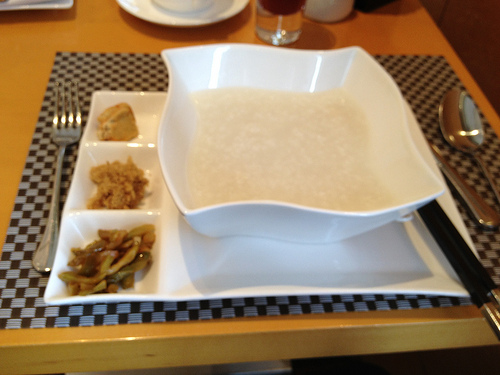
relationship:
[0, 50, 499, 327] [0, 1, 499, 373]
placemat on table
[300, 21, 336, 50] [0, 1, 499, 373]
shadow on table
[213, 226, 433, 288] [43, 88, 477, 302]
shadow on plate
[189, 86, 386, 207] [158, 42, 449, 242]
soup in bowl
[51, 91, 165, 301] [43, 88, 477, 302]
sections on plate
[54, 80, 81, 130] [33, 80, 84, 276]
tines on fork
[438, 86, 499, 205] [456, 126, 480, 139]
spoon reflecting light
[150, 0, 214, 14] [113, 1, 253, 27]
mug on saucer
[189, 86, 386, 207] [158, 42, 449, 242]
soup inside bowl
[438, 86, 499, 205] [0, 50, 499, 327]
spoon on placemat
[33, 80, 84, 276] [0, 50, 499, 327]
fork on placemat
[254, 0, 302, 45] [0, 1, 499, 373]
glass on table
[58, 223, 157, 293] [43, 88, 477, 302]
beans on plate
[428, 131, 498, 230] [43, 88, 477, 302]
knife next to plate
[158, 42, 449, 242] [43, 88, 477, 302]
bowl on plate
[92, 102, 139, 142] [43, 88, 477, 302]
food on plate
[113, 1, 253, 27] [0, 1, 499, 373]
saucer on table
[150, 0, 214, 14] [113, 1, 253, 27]
mug on top of saucer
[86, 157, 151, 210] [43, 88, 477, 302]
ginger on plate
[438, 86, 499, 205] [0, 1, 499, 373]
spoon on table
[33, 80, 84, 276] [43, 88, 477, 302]
fork next to plate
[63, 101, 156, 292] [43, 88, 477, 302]
food on plate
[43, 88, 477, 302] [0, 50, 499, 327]
plate on top of placemat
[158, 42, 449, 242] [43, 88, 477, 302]
bowl on top of plate